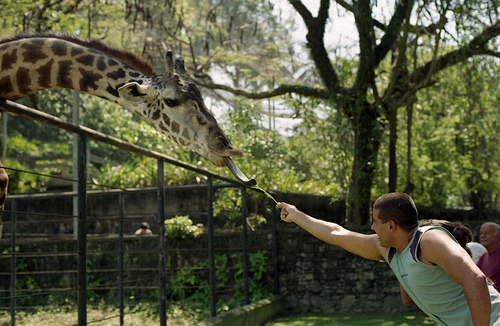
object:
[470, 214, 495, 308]
man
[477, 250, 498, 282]
shirt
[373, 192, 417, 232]
hair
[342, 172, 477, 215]
man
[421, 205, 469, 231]
backpack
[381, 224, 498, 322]
tank top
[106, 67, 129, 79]
spot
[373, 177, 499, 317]
man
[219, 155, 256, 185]
tongue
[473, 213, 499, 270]
gentleman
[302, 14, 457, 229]
tree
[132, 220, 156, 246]
person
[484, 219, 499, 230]
gray hair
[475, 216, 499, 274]
elderly man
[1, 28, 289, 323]
giraffe compound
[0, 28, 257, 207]
giraffe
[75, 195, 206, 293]
metal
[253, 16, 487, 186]
trees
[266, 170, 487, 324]
man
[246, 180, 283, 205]
leaf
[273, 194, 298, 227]
hand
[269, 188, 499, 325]
someone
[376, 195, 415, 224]
haircut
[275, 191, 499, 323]
boy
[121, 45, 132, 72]
mane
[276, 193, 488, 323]
people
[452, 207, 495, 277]
people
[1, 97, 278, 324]
metal fence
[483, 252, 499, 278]
pink shirt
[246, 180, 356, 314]
wall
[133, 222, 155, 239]
man looking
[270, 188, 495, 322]
man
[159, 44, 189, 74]
horns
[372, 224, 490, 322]
shirt